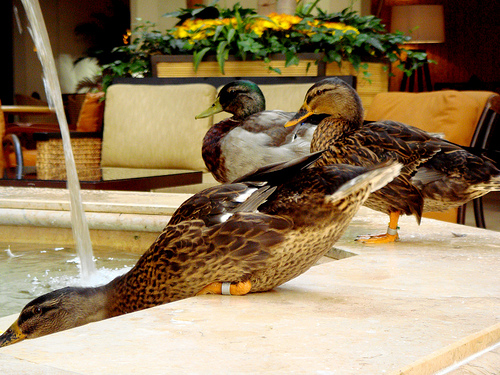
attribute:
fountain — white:
[0, 13, 178, 350]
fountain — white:
[14, 2, 100, 287]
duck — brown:
[11, 154, 395, 312]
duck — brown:
[280, 46, 498, 245]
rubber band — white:
[219, 280, 231, 296]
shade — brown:
[389, 9, 449, 49]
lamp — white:
[372, 7, 456, 88]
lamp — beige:
[389, 2, 449, 91]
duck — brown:
[165, 80, 364, 216]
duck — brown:
[294, 74, 495, 254]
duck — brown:
[191, 72, 311, 164]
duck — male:
[282, 0, 498, 175]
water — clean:
[12, 241, 130, 296]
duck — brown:
[275, 87, 476, 224]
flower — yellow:
[337, 17, 361, 35]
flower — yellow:
[319, 17, 349, 37]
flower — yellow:
[275, 20, 291, 34]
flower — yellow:
[242, 17, 265, 43]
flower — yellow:
[170, 20, 192, 48]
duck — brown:
[0, 142, 415, 351]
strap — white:
[382, 224, 403, 239]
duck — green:
[189, 73, 316, 178]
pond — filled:
[2, 185, 487, 372]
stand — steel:
[0, 129, 27, 178]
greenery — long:
[74, 1, 443, 82]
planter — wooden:
[149, 48, 419, 99]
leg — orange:
[193, 268, 269, 305]